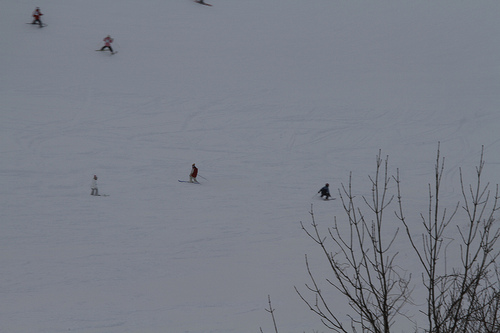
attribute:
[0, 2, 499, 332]
hill — snowy, snow covered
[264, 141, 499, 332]
tree — brown, bare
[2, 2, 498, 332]
snow — white, carved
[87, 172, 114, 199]
skater — dressed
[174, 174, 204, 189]
ski — long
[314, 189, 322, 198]
pole — long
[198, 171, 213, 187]
pole — long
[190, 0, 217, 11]
man — falling